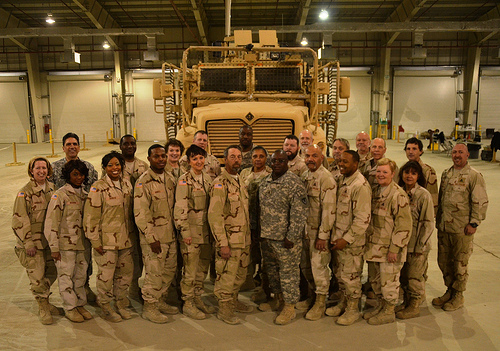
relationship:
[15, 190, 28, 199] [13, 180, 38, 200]
patches on shoulders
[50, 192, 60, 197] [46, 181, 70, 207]
patches on shoulders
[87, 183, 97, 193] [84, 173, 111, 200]
patches on shoulders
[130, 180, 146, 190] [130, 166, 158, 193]
patches on shoulders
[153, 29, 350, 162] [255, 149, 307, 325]
truck behind man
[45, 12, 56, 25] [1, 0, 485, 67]
light hanging from ceiling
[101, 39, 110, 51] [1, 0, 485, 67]
light hanging from ceiling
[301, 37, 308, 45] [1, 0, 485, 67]
light hanging from ceiling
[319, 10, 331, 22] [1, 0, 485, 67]
light hanging from ceiling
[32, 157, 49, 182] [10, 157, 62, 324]
face on woman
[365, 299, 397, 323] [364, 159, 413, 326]
boots on person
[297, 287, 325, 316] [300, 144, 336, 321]
boots on person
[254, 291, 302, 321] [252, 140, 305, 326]
boots on soldier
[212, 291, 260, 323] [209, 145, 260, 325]
boots on man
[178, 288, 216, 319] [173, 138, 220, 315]
boots on soldier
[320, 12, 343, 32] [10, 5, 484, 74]
light on ceiling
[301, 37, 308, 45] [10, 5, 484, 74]
light on ceiling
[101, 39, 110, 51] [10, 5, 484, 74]
light on ceiling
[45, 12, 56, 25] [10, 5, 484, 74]
light on ceiling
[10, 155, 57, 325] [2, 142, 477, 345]
person standing on ground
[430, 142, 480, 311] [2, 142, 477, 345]
person standing on ground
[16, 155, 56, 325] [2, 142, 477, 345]
person standing on ground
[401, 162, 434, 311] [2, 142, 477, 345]
person standing on ground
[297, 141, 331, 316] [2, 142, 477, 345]
person standing on ground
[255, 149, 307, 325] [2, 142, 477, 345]
man standing on ground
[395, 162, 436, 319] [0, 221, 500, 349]
person standing on ground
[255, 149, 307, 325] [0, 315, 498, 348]
man standing on ground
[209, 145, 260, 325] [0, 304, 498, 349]
man standing on ground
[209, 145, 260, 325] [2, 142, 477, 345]
man standing on ground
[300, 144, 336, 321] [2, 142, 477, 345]
person standing on ground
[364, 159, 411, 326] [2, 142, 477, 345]
person standing on ground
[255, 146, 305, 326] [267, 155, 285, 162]
man wearing glasses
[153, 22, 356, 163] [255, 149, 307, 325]
truck behind man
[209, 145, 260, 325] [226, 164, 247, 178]
man has a beard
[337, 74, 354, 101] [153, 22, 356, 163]
mirror on right side of truck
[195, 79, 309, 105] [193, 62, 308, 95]
wipes on windshield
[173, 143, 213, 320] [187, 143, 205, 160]
soldier has hair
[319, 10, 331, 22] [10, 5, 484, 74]
light on ceiling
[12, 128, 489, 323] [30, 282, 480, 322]
military personnel wearing boots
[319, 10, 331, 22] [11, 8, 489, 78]
light on ceiling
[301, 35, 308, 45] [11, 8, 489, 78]
light on ceiling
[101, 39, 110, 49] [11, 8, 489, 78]
light on ceiling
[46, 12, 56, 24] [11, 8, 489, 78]
light on ceiling